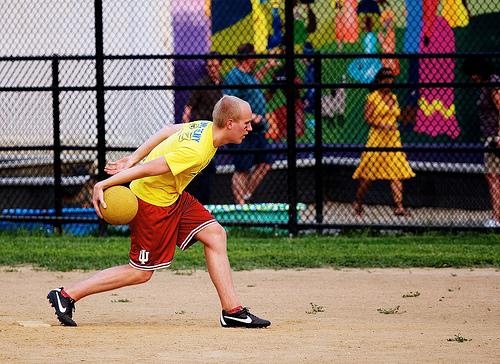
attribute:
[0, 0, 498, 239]
fence — black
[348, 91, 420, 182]
dress — yellow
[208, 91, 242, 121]
hair — short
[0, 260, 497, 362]
dirt — light, brown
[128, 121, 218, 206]
t-shirt — yellow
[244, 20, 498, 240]
fence — black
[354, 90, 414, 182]
dress — yellow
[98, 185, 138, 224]
kickball — yellow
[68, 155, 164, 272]
kickball — yellow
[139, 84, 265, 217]
boy — wearing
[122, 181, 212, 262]
shorts — burgundy